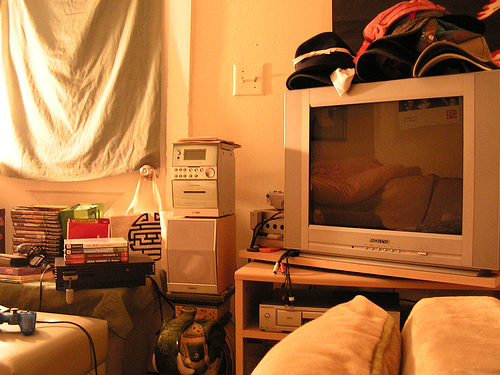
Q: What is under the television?
A: A DVD player.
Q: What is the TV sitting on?
A: A stand.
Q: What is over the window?
A: A sheet.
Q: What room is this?
A: A living room.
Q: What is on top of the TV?
A: Hats.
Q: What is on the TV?
A: The TV is off.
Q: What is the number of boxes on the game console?
A: Four.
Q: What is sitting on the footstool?
A: A game controller.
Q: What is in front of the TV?
A: A sofa.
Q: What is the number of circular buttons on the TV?
A: Six.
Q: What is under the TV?
A: A DVD player.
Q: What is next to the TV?
A: A stereo system with speakers.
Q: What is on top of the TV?
A: A stack of hats.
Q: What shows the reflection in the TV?
A: A couch.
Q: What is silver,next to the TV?
A: A stereo system.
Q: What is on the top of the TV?
A: Assorted hats and caps.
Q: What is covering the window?
A: A white sheet.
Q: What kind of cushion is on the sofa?
A: White cushion.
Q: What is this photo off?
A: A room.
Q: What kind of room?
A: A bedroom.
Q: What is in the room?
A: A stand.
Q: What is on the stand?
A: A tv.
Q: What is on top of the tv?
A: Clothes.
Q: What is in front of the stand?
A: A couch.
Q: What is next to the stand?
A: A stereo system.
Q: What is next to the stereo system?
A: A table.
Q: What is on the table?
A: A cloth.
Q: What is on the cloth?
A: Movies.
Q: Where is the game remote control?
A: On the ottoman.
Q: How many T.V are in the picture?
A: One.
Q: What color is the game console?
A: Black.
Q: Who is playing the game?
A: No one.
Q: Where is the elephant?
A: On the floor.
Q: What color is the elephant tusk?
A: Green.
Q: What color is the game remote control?
A: Blue.